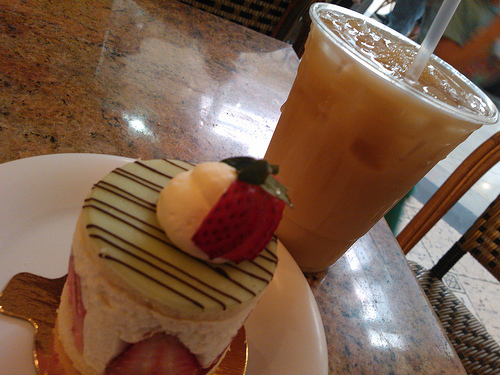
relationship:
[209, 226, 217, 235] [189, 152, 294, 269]
seed topping strawberry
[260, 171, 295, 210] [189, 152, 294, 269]
leaf attached to strawberry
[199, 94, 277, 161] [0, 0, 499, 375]
light shining on granite counter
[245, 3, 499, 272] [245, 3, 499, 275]
clear cup containing ice cubes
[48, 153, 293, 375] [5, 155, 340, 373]
appetizer dish sitting on top of plate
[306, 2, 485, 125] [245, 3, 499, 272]
edge lining clear cup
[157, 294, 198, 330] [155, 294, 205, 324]
part of edge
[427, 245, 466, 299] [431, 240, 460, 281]
part of chair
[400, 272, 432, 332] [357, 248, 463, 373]
edge of table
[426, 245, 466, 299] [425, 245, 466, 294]
part of stand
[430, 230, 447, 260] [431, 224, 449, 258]
part of floor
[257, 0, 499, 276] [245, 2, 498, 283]
beverage in clear cup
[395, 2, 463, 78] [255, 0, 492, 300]
clear straw in drink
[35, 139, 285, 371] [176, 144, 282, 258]
pastry with strawberries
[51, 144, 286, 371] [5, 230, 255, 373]
pastry on gold platter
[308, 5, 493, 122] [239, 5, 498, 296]
ice cubes in drink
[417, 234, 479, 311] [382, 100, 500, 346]
square design in floor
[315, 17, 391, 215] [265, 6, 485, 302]
beverage in cup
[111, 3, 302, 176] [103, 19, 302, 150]
reflection of sunlight